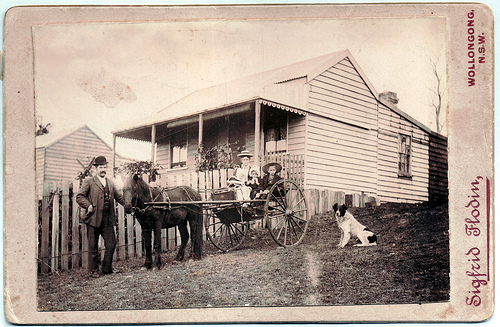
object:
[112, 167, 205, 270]
horse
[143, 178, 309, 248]
carriage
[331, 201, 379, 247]
dog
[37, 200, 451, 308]
grass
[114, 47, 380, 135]
roof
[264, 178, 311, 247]
wheel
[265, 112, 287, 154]
window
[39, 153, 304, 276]
fence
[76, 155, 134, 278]
man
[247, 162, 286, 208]
child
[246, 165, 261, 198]
child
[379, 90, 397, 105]
chimney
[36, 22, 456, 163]
sky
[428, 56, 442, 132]
tree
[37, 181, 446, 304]
yard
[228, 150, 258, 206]
mother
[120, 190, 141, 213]
reigns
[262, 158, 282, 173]
hat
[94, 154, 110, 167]
hat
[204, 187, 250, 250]
wheel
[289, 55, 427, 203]
slat